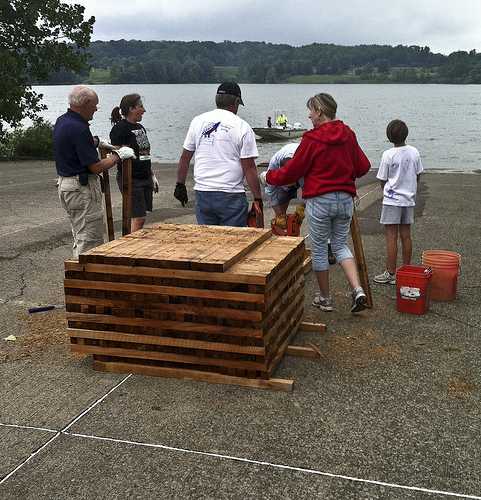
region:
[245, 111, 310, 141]
Fishing boat with two occupants.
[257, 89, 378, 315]
A woman with a wooden plank participating in repairs.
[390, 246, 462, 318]
Buckets to hold hardware for docks.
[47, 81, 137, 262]
A man with gloves ready to work.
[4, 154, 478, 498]
The landing area of a boat ramp.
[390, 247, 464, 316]
two red buckets on the ground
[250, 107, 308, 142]
two people in a boat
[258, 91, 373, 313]
a woman in a red hoodie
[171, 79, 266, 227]
a man in white with a dark hat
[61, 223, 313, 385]
a large stack of wood on the ground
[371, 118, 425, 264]
a young person standing near some buckets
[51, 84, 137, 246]
an older man with white gloves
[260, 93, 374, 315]
a woman in red holding a piece of wood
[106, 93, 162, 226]
a woman in dark clothes near a stack of wood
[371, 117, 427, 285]
person standing near the water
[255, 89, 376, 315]
person standing near the water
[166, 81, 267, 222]
person standing near the water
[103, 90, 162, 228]
person standing near the water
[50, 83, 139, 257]
person standing near the water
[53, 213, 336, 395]
medium sized stack of wet lumber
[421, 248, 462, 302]
orange bucket made of plastic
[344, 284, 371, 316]
a gray and white shoe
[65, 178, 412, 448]
wood that is piled up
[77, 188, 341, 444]
wood on the ground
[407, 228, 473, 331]
two orange bucks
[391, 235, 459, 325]
two orange bucks outside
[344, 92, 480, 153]
a body of water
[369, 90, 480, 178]
a body of calm water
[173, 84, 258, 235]
a man wearing a hat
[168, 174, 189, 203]
a man wearing a glvoe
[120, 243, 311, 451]
these are pallets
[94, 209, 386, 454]
the pallets are wooden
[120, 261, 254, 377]
the wood is brown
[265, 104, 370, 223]
the woman has a hoodie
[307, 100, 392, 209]
the hoodie is red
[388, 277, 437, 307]
the buckets is red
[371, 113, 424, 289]
person standing near a stack of wood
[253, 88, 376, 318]
person standing near a stack of wood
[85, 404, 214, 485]
a view of road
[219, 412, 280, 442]
a view of sand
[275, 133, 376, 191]
a view of jacket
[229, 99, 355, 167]
a view of boat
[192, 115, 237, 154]
a view of mark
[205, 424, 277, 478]
a view of road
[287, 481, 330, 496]
a view of sand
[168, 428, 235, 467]
a view of line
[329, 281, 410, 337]
a view of shoes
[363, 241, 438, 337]
a view of box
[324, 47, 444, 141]
a view of water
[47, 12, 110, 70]
a view of leaves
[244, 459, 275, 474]
a view of line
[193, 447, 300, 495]
a view of road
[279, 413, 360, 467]
a view of stones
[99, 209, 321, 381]
a view of wood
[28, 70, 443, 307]
a group of people